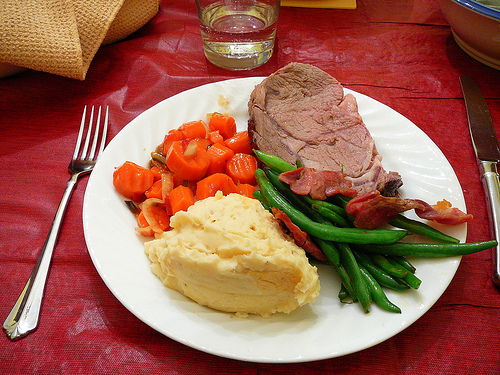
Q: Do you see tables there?
A: Yes, there is a table.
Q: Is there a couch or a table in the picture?
A: Yes, there is a table.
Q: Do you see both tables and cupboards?
A: No, there is a table but no cupboards.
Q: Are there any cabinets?
A: No, there are no cabinets.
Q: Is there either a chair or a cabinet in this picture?
A: No, there are no cabinets or chairs.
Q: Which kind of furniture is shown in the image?
A: The furniture is a table.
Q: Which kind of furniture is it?
A: The piece of furniture is a table.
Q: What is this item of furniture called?
A: This is a table.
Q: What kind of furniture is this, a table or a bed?
A: This is a table.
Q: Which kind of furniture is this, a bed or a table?
A: This is a table.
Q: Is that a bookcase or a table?
A: That is a table.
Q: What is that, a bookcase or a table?
A: That is a table.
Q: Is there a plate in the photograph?
A: Yes, there is a plate.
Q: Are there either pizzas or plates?
A: Yes, there is a plate.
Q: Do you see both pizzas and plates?
A: No, there is a plate but no pizzas.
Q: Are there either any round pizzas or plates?
A: Yes, there is a round plate.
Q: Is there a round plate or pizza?
A: Yes, there is a round plate.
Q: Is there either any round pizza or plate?
A: Yes, there is a round plate.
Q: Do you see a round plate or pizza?
A: Yes, there is a round plate.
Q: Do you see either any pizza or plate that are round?
A: Yes, the plate is round.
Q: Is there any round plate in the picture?
A: Yes, there is a round plate.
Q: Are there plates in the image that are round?
A: Yes, there is a plate that is round.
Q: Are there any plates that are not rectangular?
A: Yes, there is a round plate.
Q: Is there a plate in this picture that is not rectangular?
A: Yes, there is a round plate.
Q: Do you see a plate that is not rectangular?
A: Yes, there is a round plate.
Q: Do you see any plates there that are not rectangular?
A: Yes, there is a round plate.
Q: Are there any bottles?
A: No, there are no bottles.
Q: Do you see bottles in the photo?
A: No, there are no bottles.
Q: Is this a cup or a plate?
A: This is a plate.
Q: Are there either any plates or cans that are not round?
A: No, there is a plate but it is round.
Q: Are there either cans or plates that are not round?
A: No, there is a plate but it is round.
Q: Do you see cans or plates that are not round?
A: No, there is a plate but it is round.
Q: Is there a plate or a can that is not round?
A: No, there is a plate but it is round.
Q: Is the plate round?
A: Yes, the plate is round.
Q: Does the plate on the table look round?
A: Yes, the plate is round.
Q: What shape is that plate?
A: The plate is round.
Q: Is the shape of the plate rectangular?
A: No, the plate is round.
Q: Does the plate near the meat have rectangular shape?
A: No, the plate is round.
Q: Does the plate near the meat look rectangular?
A: No, the plate is round.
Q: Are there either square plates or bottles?
A: No, there is a plate but it is round.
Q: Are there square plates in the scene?
A: No, there is a plate but it is round.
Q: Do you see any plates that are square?
A: No, there is a plate but it is round.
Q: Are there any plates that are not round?
A: No, there is a plate but it is round.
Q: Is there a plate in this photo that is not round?
A: No, there is a plate but it is round.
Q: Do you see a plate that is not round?
A: No, there is a plate but it is round.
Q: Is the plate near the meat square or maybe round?
A: The plate is round.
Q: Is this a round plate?
A: Yes, this is a round plate.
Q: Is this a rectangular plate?
A: No, this is a round plate.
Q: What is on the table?
A: The plate is on the table.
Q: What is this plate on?
A: The plate is on the table.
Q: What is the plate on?
A: The plate is on the table.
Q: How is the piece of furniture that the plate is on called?
A: The piece of furniture is a table.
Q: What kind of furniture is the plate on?
A: The plate is on the table.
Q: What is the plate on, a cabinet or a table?
A: The plate is on a table.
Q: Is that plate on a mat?
A: No, the plate is on a table.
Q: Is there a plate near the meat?
A: Yes, there is a plate near the meat.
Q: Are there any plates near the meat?
A: Yes, there is a plate near the meat.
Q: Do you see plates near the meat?
A: Yes, there is a plate near the meat.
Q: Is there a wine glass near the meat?
A: No, there is a plate near the meat.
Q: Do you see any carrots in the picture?
A: Yes, there is a carrot.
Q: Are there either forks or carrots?
A: Yes, there is a carrot.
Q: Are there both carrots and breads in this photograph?
A: No, there is a carrot but no breads.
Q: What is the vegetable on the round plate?
A: The vegetable is a carrot.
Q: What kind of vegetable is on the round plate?
A: The vegetable is a carrot.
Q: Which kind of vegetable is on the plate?
A: The vegetable is a carrot.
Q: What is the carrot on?
A: The carrot is on the plate.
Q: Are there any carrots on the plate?
A: Yes, there is a carrot on the plate.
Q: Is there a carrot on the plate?
A: Yes, there is a carrot on the plate.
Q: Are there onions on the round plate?
A: No, there is a carrot on the plate.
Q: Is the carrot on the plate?
A: Yes, the carrot is on the plate.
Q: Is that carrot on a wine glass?
A: No, the carrot is on the plate.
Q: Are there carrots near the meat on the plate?
A: Yes, there is a carrot near the meat.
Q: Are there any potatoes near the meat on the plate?
A: No, there is a carrot near the meat.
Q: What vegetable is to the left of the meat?
A: The vegetable is a carrot.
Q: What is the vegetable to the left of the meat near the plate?
A: The vegetable is a carrot.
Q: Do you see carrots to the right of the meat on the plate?
A: No, the carrot is to the left of the meat.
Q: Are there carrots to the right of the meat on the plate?
A: No, the carrot is to the left of the meat.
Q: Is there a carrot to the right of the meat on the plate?
A: No, the carrot is to the left of the meat.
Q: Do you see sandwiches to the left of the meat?
A: No, there is a carrot to the left of the meat.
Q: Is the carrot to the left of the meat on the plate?
A: Yes, the carrot is to the left of the meat.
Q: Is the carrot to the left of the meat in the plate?
A: Yes, the carrot is to the left of the meat.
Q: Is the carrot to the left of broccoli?
A: No, the carrot is to the left of the meat.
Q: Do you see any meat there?
A: Yes, there is meat.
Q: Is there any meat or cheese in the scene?
A: Yes, there is meat.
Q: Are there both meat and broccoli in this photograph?
A: No, there is meat but no broccoli.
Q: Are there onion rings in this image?
A: No, there are no onion rings.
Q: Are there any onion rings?
A: No, there are no onion rings.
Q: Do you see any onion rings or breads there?
A: No, there are no onion rings or breads.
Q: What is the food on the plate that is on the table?
A: The food is meat.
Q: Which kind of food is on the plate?
A: The food is meat.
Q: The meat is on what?
A: The meat is on the plate.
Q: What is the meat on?
A: The meat is on the plate.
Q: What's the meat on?
A: The meat is on the plate.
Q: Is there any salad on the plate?
A: No, there is meat on the plate.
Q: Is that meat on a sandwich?
A: No, the meat is on the plate.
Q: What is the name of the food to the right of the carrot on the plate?
A: The food is meat.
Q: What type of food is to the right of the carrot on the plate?
A: The food is meat.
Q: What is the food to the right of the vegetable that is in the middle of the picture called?
A: The food is meat.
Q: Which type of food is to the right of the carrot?
A: The food is meat.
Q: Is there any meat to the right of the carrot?
A: Yes, there is meat to the right of the carrot.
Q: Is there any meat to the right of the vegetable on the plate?
A: Yes, there is meat to the right of the carrot.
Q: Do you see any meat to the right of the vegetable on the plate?
A: Yes, there is meat to the right of the carrot.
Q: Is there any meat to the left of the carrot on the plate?
A: No, the meat is to the right of the carrot.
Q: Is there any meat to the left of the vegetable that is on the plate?
A: No, the meat is to the right of the carrot.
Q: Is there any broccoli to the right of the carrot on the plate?
A: No, there is meat to the right of the carrot.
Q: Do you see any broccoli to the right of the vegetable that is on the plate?
A: No, there is meat to the right of the carrot.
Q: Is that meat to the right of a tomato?
A: No, the meat is to the right of the carrot.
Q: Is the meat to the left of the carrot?
A: No, the meat is to the right of the carrot.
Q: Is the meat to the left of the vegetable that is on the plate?
A: No, the meat is to the right of the carrot.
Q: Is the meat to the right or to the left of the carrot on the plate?
A: The meat is to the right of the carrot.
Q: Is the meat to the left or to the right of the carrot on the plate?
A: The meat is to the right of the carrot.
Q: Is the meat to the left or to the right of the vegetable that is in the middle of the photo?
A: The meat is to the right of the carrot.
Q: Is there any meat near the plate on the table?
A: Yes, there is meat near the plate.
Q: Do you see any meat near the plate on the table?
A: Yes, there is meat near the plate.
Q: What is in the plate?
A: The meat is in the plate.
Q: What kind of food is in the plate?
A: The food is meat.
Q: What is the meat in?
A: The meat is in the plate.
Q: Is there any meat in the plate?
A: Yes, there is meat in the plate.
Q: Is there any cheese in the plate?
A: No, there is meat in the plate.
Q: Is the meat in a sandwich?
A: No, the meat is in the plate.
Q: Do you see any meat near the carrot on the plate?
A: Yes, there is meat near the carrot.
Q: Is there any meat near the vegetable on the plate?
A: Yes, there is meat near the carrot.